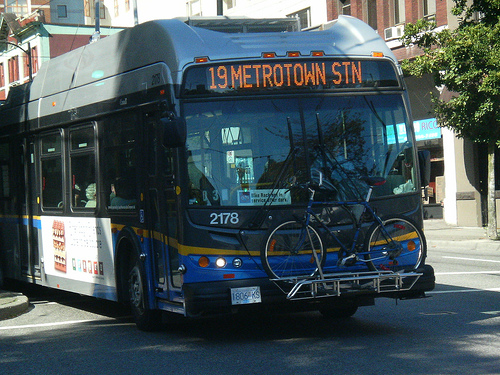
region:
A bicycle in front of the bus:
[267, 172, 452, 299]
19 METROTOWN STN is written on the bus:
[190, 57, 383, 112]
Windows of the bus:
[10, 82, 165, 239]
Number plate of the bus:
[225, 285, 265, 328]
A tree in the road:
[408, 0, 493, 196]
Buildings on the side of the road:
[1, 1, 446, 93]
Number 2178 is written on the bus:
[196, 203, 253, 243]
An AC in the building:
[380, 13, 413, 58]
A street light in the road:
[1, 33, 41, 89]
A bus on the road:
[10, 3, 440, 343]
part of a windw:
[228, 150, 254, 206]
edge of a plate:
[235, 293, 255, 315]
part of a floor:
[397, 325, 412, 360]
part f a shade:
[396, 332, 446, 360]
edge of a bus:
[245, 298, 267, 320]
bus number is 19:
[183, 45, 237, 93]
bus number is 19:
[199, 56, 239, 101]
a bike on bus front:
[239, 145, 423, 319]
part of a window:
[346, 98, 391, 169]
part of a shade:
[392, 318, 431, 353]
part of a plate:
[234, 301, 239, 303]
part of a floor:
[363, 320, 380, 355]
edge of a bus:
[204, 302, 237, 337]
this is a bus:
[20, 17, 397, 307]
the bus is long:
[45, 16, 397, 311]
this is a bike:
[265, 164, 404, 284]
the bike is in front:
[260, 170, 407, 280]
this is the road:
[370, 311, 442, 365]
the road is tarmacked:
[34, 321, 106, 372]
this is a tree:
[439, 25, 494, 122]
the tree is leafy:
[428, 12, 490, 128]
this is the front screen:
[223, 92, 389, 187]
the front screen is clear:
[228, 86, 391, 184]